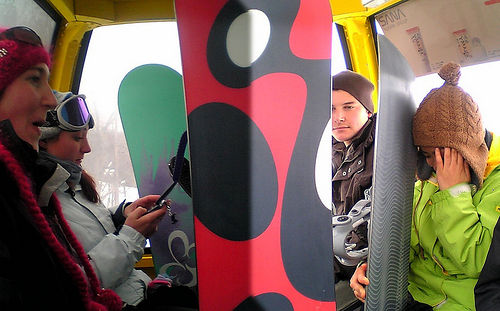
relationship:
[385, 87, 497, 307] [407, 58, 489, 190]
person in ski cap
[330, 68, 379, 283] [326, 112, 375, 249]
man wearing jacket jacket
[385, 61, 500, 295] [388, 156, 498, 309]
person in jacket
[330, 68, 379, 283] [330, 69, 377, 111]
man in beanie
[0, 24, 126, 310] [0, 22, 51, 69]
female in cap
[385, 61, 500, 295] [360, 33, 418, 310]
person with board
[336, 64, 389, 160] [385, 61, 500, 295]
face on person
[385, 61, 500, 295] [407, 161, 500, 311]
person in green jacket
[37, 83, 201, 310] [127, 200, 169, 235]
girl has hand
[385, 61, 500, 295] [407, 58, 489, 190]
person in ski cap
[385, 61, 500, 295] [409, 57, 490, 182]
person has beany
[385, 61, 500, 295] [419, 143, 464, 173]
person has face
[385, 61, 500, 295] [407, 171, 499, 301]
person in green jacket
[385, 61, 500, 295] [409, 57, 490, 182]
person wearing beany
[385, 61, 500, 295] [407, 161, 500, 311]
person wearing green jacket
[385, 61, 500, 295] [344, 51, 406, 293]
person holding board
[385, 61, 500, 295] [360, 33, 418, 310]
person holding board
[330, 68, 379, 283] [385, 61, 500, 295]
man next to person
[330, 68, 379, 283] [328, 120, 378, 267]
man wearing jacket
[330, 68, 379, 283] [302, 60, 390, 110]
man wearing beanie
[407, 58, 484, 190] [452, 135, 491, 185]
ski cap with flaps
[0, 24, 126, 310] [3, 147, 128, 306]
female in sweater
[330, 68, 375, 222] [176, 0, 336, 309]
man at snowboard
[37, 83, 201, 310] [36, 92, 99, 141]
girl in goggles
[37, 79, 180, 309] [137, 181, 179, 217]
girl on cell phone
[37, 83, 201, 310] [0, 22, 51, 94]
girl has on cap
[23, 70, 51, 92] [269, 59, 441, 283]
eye of woman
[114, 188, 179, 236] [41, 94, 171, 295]
hands of woman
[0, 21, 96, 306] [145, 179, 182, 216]
female texting on cellular phone